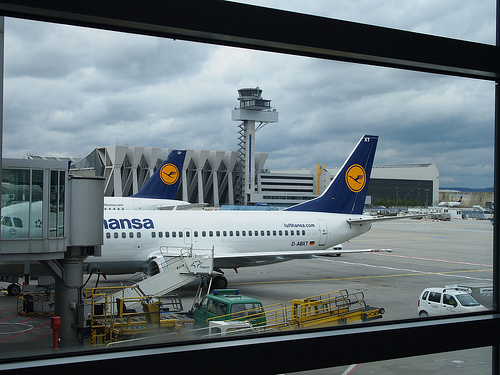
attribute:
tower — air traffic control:
[231, 86, 278, 203]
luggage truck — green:
[193, 286, 267, 323]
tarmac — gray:
[232, 215, 493, 374]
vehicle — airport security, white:
[416, 284, 486, 318]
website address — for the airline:
[284, 220, 318, 230]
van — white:
[417, 284, 488, 319]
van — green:
[186, 290, 272, 332]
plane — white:
[0, 129, 427, 317]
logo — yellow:
[342, 160, 369, 193]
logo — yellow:
[156, 160, 178, 185]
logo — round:
[343, 161, 370, 192]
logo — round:
[156, 160, 181, 184]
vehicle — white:
[418, 283, 486, 313]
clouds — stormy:
[0, 0, 498, 188]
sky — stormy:
[0, 6, 498, 188]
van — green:
[188, 285, 268, 334]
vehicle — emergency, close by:
[187, 285, 268, 332]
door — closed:
[315, 219, 331, 249]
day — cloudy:
[199, 41, 489, 165]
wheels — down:
[5, 281, 24, 298]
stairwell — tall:
[233, 120, 250, 208]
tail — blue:
[283, 132, 381, 216]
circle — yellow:
[344, 160, 370, 194]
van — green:
[187, 285, 268, 339]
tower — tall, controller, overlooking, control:
[229, 84, 281, 209]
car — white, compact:
[415, 284, 493, 321]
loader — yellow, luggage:
[79, 280, 196, 350]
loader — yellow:
[204, 285, 389, 335]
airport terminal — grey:
[25, 80, 442, 212]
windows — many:
[256, 173, 314, 182]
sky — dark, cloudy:
[4, 16, 209, 153]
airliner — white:
[2, 131, 435, 298]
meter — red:
[49, 310, 65, 350]